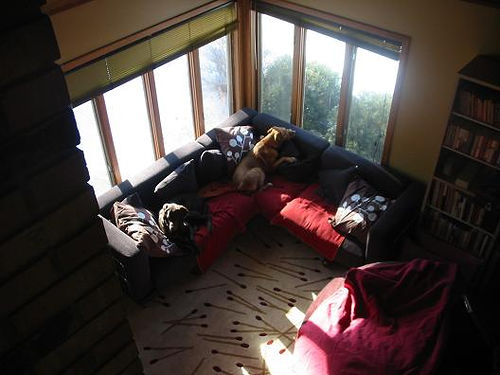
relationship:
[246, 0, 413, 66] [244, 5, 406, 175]
blinds on window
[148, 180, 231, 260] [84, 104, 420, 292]
dog on couch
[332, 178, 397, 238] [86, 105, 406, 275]
pillow on couch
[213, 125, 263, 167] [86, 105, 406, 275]
pillow on couch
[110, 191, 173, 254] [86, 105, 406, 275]
pillow on couch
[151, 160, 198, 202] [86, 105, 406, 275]
pillow on couch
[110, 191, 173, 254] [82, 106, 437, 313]
pillow on couch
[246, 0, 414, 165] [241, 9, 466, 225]
blinds on wall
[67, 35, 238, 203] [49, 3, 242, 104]
blinds on wall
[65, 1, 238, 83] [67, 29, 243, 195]
blinds above window